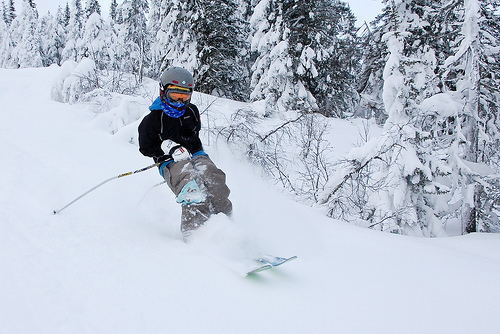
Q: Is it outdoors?
A: Yes, it is outdoors.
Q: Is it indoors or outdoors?
A: It is outdoors.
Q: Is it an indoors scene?
A: No, it is outdoors.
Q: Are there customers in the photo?
A: No, there are no customers.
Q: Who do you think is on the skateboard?
A: The guy is on the skateboard.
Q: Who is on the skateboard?
A: The guy is on the skateboard.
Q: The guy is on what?
A: The guy is on the skateboard.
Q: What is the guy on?
A: The guy is on the skateboard.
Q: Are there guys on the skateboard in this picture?
A: Yes, there is a guy on the skateboard.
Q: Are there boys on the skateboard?
A: No, there is a guy on the skateboard.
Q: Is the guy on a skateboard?
A: Yes, the guy is on a skateboard.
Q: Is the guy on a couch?
A: No, the guy is on a skateboard.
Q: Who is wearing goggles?
A: The guy is wearing goggles.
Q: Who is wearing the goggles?
A: The guy is wearing goggles.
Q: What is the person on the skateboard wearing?
A: The guy is wearing goggles.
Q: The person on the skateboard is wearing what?
A: The guy is wearing goggles.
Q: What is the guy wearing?
A: The guy is wearing goggles.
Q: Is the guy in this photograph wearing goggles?
A: Yes, the guy is wearing goggles.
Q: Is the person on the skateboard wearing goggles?
A: Yes, the guy is wearing goggles.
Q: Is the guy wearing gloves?
A: No, the guy is wearing goggles.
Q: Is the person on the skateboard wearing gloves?
A: No, the guy is wearing goggles.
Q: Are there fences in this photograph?
A: No, there are no fences.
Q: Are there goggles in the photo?
A: Yes, there are goggles.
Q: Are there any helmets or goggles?
A: Yes, there are goggles.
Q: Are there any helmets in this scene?
A: Yes, there is a helmet.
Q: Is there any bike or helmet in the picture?
A: Yes, there is a helmet.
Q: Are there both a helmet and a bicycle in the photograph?
A: No, there is a helmet but no bicycles.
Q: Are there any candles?
A: No, there are no candles.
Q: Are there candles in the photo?
A: No, there are no candles.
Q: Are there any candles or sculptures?
A: No, there are no candles or sculptures.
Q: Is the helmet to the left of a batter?
A: No, the helmet is to the left of a pine tree.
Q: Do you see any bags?
A: No, there are no bags.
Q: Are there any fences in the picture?
A: No, there are no fences.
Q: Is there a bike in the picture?
A: No, there are no bikes.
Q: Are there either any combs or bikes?
A: No, there are no bikes or combs.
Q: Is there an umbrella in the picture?
A: No, there are no umbrellas.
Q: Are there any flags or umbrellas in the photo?
A: No, there are no umbrellas or flags.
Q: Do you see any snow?
A: Yes, there is snow.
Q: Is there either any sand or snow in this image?
A: Yes, there is snow.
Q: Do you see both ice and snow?
A: No, there is snow but no ice.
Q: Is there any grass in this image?
A: No, there is no grass.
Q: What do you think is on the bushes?
A: The snow is on the bushes.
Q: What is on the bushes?
A: The snow is on the bushes.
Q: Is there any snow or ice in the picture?
A: Yes, there is snow.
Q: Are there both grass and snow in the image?
A: No, there is snow but no grass.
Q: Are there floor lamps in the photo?
A: No, there are no floor lamps.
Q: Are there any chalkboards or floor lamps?
A: No, there are no floor lamps or chalkboards.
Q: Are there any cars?
A: No, there are no cars.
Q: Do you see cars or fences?
A: No, there are no cars or fences.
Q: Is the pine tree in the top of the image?
A: Yes, the pine tree is in the top of the image.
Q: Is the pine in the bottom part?
A: No, the pine is in the top of the image.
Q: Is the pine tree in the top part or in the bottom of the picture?
A: The pine tree is in the top of the image.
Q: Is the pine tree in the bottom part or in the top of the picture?
A: The pine tree is in the top of the image.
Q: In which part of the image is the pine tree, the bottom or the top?
A: The pine tree is in the top of the image.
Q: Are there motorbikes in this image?
A: No, there are no motorbikes.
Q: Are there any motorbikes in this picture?
A: No, there are no motorbikes.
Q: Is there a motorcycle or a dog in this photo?
A: No, there are no motorcycles or dogs.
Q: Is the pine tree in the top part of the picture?
A: Yes, the pine tree is in the top of the image.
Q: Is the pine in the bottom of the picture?
A: No, the pine is in the top of the image.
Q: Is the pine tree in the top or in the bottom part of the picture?
A: The pine tree is in the top of the image.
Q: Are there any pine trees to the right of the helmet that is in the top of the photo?
A: Yes, there is a pine tree to the right of the helmet.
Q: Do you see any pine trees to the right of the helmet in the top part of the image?
A: Yes, there is a pine tree to the right of the helmet.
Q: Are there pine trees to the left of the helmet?
A: No, the pine tree is to the right of the helmet.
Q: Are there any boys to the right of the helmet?
A: No, there is a pine tree to the right of the helmet.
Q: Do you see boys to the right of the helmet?
A: No, there is a pine tree to the right of the helmet.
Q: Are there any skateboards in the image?
A: Yes, there is a skateboard.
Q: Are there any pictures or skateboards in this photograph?
A: Yes, there is a skateboard.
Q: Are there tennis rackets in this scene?
A: No, there are no tennis rackets.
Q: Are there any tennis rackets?
A: No, there are no tennis rackets.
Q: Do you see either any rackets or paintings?
A: No, there are no rackets or paintings.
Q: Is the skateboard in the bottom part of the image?
A: Yes, the skateboard is in the bottom of the image.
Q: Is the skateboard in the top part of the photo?
A: No, the skateboard is in the bottom of the image.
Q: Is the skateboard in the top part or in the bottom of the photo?
A: The skateboard is in the bottom of the image.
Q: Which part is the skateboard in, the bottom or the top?
A: The skateboard is in the bottom of the image.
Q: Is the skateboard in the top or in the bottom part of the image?
A: The skateboard is in the bottom of the image.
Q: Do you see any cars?
A: No, there are no cars.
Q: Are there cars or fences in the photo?
A: No, there are no cars or fences.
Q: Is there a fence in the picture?
A: No, there are no fences.